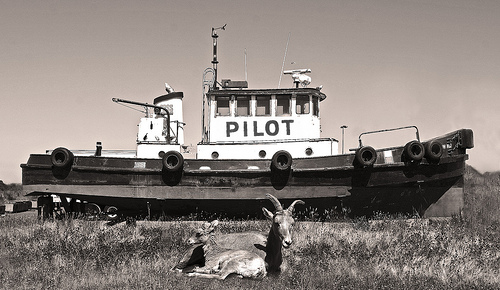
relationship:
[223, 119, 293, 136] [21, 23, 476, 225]
lettering on ship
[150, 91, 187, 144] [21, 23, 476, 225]
stack on ship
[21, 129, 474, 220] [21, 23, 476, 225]
hull on ship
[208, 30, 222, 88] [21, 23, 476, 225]
pole on ship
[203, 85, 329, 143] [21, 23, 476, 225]
structure on ship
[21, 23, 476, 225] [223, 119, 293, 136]
ship has lettering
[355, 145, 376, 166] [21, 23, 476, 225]
tire on ship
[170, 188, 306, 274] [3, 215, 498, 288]
goat on grass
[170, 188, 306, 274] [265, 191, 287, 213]
goat has horn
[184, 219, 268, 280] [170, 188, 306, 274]
baby by goat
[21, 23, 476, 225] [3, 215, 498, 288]
ship on grass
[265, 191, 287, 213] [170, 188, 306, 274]
horn of goat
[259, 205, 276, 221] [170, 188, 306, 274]
ear of goat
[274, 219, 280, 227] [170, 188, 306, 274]
eye of goat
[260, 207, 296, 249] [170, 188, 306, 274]
head of goat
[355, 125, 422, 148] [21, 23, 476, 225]
rail on ship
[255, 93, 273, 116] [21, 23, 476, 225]
window on ship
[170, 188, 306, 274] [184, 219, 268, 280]
goat and baby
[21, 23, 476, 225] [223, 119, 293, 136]
ship with lettering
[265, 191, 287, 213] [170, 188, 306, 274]
horn on goat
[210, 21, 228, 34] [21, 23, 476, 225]
vane on ship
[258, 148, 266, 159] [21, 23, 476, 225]
porthole on ship